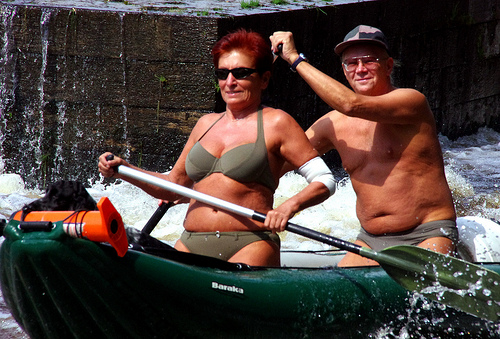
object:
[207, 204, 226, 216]
belly button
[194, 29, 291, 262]
woman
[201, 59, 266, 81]
sunglasses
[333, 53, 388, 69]
glasses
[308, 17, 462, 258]
man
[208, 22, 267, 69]
red hair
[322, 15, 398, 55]
hat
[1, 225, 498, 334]
raft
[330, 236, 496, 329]
paddle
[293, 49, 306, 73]
watch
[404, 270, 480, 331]
splashes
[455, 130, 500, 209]
water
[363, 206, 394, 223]
belly button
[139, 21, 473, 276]
people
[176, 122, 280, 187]
bra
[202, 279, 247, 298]
baraka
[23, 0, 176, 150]
rock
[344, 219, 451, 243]
briefs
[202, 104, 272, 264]
swimsuit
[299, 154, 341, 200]
elbow band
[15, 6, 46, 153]
rust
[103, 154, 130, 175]
handle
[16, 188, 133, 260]
equipment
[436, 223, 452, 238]
logo